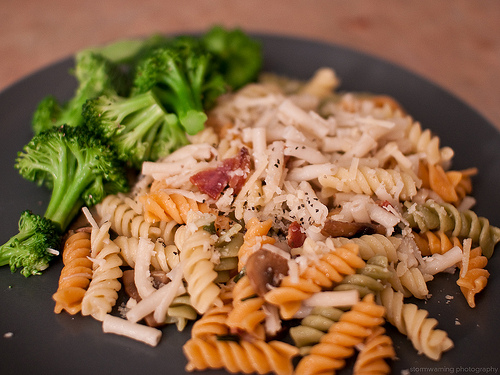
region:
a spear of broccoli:
[15, 126, 129, 222]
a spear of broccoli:
[2, 211, 51, 276]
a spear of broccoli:
[82, 85, 162, 165]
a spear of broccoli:
[132, 33, 223, 139]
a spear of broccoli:
[199, 23, 262, 87]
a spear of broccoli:
[62, 50, 130, 128]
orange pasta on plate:
[101, 157, 496, 358]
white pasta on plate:
[21, 162, 313, 330]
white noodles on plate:
[171, 73, 383, 199]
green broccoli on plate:
[31, 50, 202, 238]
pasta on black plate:
[16, 111, 461, 371]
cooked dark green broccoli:
[29, 61, 272, 257]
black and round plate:
[29, 45, 497, 335]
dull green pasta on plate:
[274, 155, 471, 352]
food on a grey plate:
[0, 24, 498, 373]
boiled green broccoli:
[1, 23, 261, 275]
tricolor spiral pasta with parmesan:
[59, 67, 496, 372]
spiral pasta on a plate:
[52, 63, 499, 373]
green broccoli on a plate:
[0, 17, 262, 282]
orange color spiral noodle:
[266, 245, 361, 321]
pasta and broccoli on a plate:
[1, 24, 497, 373]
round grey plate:
[0, 28, 497, 373]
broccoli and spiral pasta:
[2, 23, 496, 373]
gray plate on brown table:
[8, 7, 494, 369]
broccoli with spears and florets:
[6, 30, 261, 281]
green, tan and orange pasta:
[55, 75, 491, 372]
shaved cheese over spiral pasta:
[120, 75, 435, 347]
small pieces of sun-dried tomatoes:
[187, 140, 247, 200]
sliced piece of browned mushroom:
[240, 240, 290, 292]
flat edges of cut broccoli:
[140, 85, 175, 126]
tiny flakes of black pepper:
[195, 125, 330, 260]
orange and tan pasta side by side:
[48, 225, 123, 320]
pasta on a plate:
[157, 120, 499, 350]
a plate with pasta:
[236, 148, 451, 371]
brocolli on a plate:
[27, 24, 308, 274]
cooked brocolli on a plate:
[15, 24, 350, 351]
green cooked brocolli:
[29, 27, 264, 249]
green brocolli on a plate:
[22, 36, 347, 265]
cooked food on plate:
[12, 25, 391, 370]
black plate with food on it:
[2, 29, 495, 374]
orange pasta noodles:
[70, 169, 487, 367]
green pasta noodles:
[148, 197, 488, 360]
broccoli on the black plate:
[8, 36, 248, 281]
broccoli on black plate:
[0, 26, 498, 373]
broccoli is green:
[3, 26, 272, 276]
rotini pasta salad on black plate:
[1, 33, 498, 374]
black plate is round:
[1, 30, 496, 374]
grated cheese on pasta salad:
[54, 66, 498, 373]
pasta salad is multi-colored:
[51, 66, 498, 372]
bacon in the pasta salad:
[0, 30, 496, 374]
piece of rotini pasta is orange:
[264, 243, 368, 320]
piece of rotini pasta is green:
[289, 256, 391, 348]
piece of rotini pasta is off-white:
[172, 221, 225, 311]